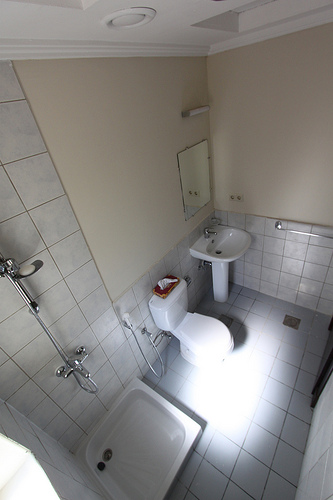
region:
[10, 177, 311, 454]
This is a bathroom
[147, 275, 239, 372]
This is a toilet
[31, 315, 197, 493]
A shower stall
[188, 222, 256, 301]
This is the bathroom sink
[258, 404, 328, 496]
Tiles cover the floor and wall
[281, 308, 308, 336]
A drain prevents water from collecting on the floor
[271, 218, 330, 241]
A towel rack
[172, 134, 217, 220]
A mirror is on the wall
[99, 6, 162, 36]
A bathroom vent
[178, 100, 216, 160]
A light is above the mirror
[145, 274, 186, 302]
the tissue box is multi-colored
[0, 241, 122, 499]
this is a shower-only stall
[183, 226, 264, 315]
white pedestal sink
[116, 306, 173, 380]
shower head outside of shower stall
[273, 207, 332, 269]
towel rack is free of towels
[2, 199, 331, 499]
the bathroom has tile floors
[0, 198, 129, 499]
shower stall is lined with tile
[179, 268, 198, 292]
empty toilet paper dispenser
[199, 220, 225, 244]
silver faucet on pedestal sink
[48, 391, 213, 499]
moderately clean shower stall floor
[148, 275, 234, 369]
A white toilet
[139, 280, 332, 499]
A white tile floor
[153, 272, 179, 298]
A box of tissues on a toilet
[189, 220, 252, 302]
A white sink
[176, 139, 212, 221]
A mirror on the wall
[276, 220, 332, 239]
A metal bar on the wall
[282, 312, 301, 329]
A drain in the floor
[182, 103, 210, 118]
A light on the wall above the mirror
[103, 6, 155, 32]
A light on the ceiling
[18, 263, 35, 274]
A bar of soap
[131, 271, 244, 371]
the white toilet is closed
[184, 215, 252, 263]
the white sink is clean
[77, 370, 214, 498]
the shower base is small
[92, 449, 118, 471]
the drain of the shower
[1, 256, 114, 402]
the faucet for the shower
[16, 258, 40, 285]
the soap is in a holder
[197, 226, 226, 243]
the faucet of the sink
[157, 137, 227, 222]
the mirror on the wall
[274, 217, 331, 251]
the handrail on the wall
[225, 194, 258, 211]
the socket on the wall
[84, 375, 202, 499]
an open drain and shower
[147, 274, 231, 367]
a white toilet and tank next to the sink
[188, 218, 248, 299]
a white sink against the corner wall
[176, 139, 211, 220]
a mirror on the wall above the sink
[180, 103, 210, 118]
a fluorescent light above the mirror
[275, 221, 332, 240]
a metal towel rack mounted on the wall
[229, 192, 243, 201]
an electric outlet fixture on the wall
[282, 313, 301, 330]
a grated water drain on the floor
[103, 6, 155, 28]
a recessed light in the ceiling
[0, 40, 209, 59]
white wall and ceiling molding